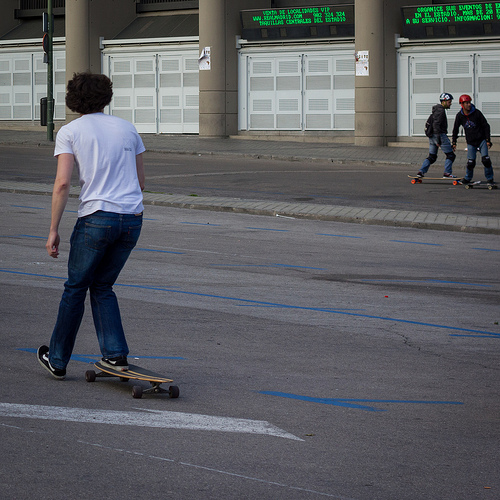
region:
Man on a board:
[80, 348, 194, 410]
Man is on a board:
[80, 352, 190, 407]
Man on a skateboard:
[80, 355, 186, 407]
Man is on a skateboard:
[82, 350, 186, 408]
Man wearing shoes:
[31, 338, 134, 385]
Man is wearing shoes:
[35, 337, 145, 382]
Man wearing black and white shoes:
[35, 337, 140, 389]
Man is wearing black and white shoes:
[32, 342, 134, 384]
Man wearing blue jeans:
[45, 204, 152, 370]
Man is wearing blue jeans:
[44, 202, 154, 378]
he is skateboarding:
[27, 54, 219, 406]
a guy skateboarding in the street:
[24, 44, 195, 414]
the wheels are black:
[116, 380, 211, 396]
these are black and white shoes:
[26, 332, 152, 385]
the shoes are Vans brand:
[27, 326, 158, 404]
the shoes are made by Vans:
[9, 333, 154, 395]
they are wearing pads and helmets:
[404, 49, 495, 215]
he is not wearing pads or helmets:
[15, 44, 227, 397]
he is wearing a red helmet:
[457, 81, 492, 181]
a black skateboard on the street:
[73, 351, 186, 402]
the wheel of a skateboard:
[128, 382, 182, 398]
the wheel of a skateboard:
[83, 367, 132, 382]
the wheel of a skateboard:
[410, 177, 422, 186]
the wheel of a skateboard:
[450, 177, 459, 189]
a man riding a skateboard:
[19, 72, 191, 409]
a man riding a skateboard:
[401, 87, 464, 187]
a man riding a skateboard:
[448, 94, 499, 190]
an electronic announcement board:
[240, 0, 350, 34]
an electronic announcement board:
[395, 0, 498, 25]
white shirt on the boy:
[51, 112, 148, 217]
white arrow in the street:
[1, 400, 307, 443]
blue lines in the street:
[258, 383, 465, 413]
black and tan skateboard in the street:
[81, 357, 183, 403]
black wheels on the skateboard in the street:
[82, 368, 182, 401]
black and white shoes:
[36, 342, 131, 380]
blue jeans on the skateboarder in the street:
[43, 204, 145, 371]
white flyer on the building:
[353, 48, 371, 78]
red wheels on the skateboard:
[407, 175, 460, 186]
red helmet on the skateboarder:
[458, 93, 473, 107]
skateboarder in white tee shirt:
[35, 64, 150, 385]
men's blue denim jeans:
[42, 201, 146, 377]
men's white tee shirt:
[45, 112, 150, 222]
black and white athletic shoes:
[31, 338, 132, 378]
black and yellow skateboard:
[78, 354, 184, 408]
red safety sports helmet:
[454, 92, 473, 107]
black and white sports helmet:
[437, 91, 454, 101]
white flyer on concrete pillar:
[348, 45, 373, 78]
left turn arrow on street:
[1, 395, 308, 447]